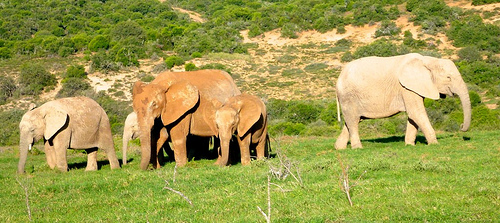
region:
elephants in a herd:
[13, 38, 480, 183]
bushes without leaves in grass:
[255, 159, 368, 221]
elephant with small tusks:
[12, 89, 121, 183]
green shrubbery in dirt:
[228, 1, 350, 58]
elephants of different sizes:
[10, 54, 276, 179]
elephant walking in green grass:
[320, 43, 485, 160]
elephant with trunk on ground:
[8, 84, 125, 191]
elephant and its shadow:
[324, 41, 478, 151]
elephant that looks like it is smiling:
[326, 48, 472, 155]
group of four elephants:
[9, 48, 281, 181]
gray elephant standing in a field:
[327, 51, 482, 156]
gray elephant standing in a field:
[12, 91, 122, 183]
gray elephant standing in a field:
[118, 109, 143, 169]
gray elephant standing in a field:
[210, 91, 272, 173]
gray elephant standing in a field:
[129, 61, 249, 181]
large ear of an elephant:
[42, 107, 69, 144]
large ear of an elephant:
[158, 78, 198, 128]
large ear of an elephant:
[234, 97, 264, 138]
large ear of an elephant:
[395, 53, 442, 104]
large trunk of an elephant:
[455, 79, 475, 141]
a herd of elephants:
[2, 22, 495, 192]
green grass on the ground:
[0, 137, 499, 221]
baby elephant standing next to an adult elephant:
[117, 64, 287, 169]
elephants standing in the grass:
[6, 40, 486, 180]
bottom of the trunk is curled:
[450, 82, 475, 144]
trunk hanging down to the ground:
[13, 129, 40, 179]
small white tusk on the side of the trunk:
[24, 142, 34, 150]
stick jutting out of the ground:
[248, 165, 278, 221]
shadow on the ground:
[354, 130, 474, 146]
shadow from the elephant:
[58, 155, 138, 170]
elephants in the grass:
[27, 54, 422, 171]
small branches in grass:
[237, 155, 363, 221]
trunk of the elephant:
[449, 88, 484, 138]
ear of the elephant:
[155, 68, 201, 131]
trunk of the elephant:
[14, 132, 38, 174]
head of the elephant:
[202, 90, 244, 165]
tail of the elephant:
[330, 88, 346, 125]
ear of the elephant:
[235, 92, 279, 143]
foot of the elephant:
[175, 153, 191, 161]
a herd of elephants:
[1, 18, 491, 173]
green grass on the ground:
[1, 128, 498, 220]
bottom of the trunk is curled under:
[457, 83, 474, 143]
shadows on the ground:
[46, 151, 256, 171]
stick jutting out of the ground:
[248, 170, 285, 221]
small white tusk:
[24, 142, 36, 154]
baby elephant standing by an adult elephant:
[128, 61, 283, 171]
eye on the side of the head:
[442, 73, 453, 83]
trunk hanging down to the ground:
[17, 127, 36, 176]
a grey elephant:
[11, 95, 114, 174]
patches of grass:
[264, 35, 326, 100]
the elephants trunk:
[457, 90, 479, 137]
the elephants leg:
[236, 143, 251, 160]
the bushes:
[105, 16, 152, 59]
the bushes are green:
[91, 23, 136, 70]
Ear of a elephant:
[163, 82, 200, 125]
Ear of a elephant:
[41, 108, 68, 142]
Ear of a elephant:
[238, 99, 263, 140]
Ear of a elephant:
[393, 58, 441, 107]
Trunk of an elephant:
[13, 133, 33, 173]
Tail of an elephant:
[329, 88, 346, 125]